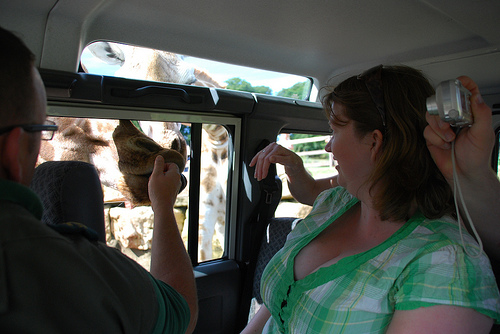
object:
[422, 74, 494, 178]
hand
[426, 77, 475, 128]
camera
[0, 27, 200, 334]
man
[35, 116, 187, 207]
giraffe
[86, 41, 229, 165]
giraffe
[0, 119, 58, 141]
glasses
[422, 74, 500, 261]
person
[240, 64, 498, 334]
lady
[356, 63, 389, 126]
sunglasses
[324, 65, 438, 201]
head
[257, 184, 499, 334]
shirt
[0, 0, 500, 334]
picture